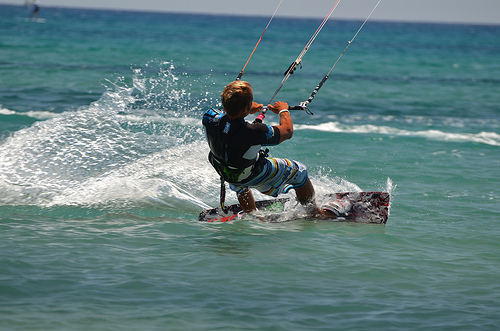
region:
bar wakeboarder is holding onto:
[217, 83, 312, 113]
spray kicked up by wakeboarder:
[10, 64, 267, 222]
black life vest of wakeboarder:
[204, 122, 265, 179]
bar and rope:
[228, 10, 375, 121]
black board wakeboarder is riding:
[191, 193, 382, 222]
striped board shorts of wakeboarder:
[227, 163, 306, 196]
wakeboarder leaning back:
[169, 90, 391, 227]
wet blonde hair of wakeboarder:
[218, 84, 252, 107]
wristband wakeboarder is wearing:
[274, 101, 288, 116]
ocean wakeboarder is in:
[16, 12, 488, 314]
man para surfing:
[181, 69, 333, 221]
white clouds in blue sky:
[13, 5, 86, 66]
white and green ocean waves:
[26, 80, 81, 150]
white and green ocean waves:
[58, 201, 131, 282]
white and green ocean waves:
[162, 260, 269, 325]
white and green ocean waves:
[250, 256, 306, 308]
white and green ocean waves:
[370, 265, 415, 305]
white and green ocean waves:
[380, 107, 435, 153]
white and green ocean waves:
[77, 35, 185, 88]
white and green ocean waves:
[376, 41, 423, 90]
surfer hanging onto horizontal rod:
[198, 7, 393, 228]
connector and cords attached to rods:
[225, 0, 385, 122]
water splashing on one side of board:
[10, 62, 356, 247]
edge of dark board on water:
[195, 190, 390, 225]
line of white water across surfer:
[2, 97, 493, 152]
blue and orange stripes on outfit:
[200, 100, 310, 200]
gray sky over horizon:
[25, 0, 495, 30]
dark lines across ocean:
[15, 20, 487, 115]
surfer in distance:
[15, 0, 47, 25]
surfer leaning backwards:
[196, 75, 346, 220]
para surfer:
[196, 67, 381, 253]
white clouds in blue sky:
[332, 6, 382, 22]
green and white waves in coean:
[15, 76, 67, 133]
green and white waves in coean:
[72, 158, 120, 201]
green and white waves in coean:
[282, 265, 333, 300]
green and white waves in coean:
[395, 252, 437, 303]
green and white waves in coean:
[95, 225, 136, 272]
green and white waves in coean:
[22, 187, 80, 247]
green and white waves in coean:
[35, 226, 115, 282]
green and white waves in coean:
[48, 30, 112, 105]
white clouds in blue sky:
[398, 10, 438, 31]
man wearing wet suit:
[156, 68, 306, 204]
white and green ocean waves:
[45, 155, 85, 212]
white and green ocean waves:
[40, 52, 116, 129]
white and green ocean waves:
[112, 195, 195, 266]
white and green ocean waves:
[358, 275, 408, 325]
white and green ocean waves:
[405, 215, 461, 291]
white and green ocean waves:
[15, 230, 100, 290]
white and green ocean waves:
[146, 46, 198, 98]